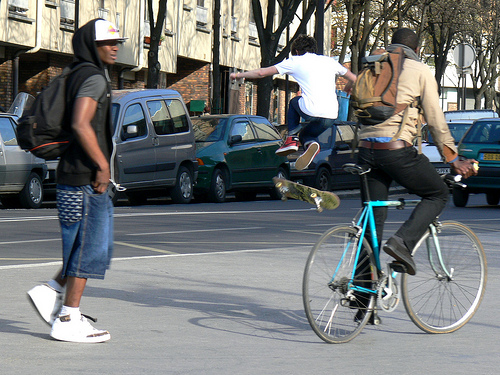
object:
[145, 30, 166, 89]
tree stem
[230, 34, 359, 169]
man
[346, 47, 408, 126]
backpack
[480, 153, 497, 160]
plate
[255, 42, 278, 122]
stem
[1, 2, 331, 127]
building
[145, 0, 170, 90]
tree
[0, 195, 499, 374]
road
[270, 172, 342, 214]
skateboard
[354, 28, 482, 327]
man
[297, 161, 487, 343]
bike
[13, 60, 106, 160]
backpack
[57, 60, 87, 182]
back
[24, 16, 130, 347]
man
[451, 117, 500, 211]
car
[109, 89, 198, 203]
car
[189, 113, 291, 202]
car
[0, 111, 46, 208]
car